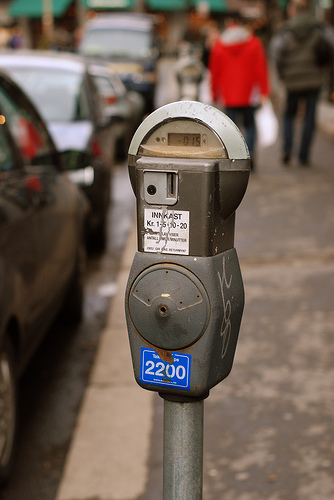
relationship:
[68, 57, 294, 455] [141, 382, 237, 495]
parking meter on pole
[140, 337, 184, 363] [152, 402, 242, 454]
rust on metal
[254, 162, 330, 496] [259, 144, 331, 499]
part of walkpath